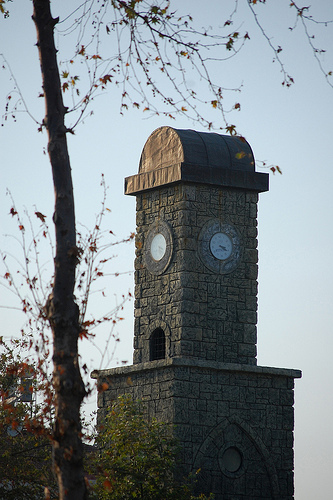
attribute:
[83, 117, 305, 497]
clock tower — stone, brown, bricked, gray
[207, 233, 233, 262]
clock — round, white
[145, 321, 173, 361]
door — round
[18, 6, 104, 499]
tree — narrow, tall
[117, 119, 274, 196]
dome — metallic, round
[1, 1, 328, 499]
sky — blue, clear, muggy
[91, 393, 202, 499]
leaves — green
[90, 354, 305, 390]
ledge — stone